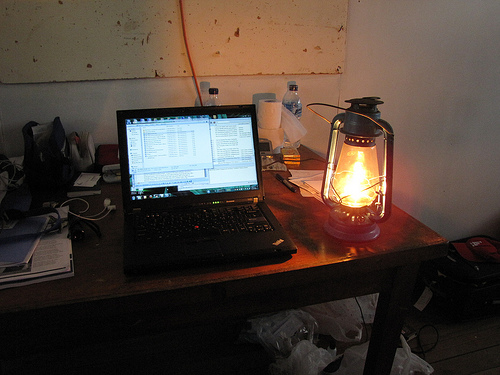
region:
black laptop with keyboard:
[108, 102, 305, 280]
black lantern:
[315, 77, 398, 272]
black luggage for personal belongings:
[445, 221, 495, 316]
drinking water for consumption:
[276, 67, 311, 169]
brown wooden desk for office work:
[1, 135, 457, 370]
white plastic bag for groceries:
[260, 315, 350, 370]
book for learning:
[0, 210, 80, 280]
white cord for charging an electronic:
[55, 185, 115, 235]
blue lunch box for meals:
[16, 115, 71, 215]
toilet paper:
[254, 92, 310, 173]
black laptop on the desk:
[116, 107, 297, 266]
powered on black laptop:
[118, 108, 296, 264]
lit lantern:
[318, 95, 398, 240]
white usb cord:
[73, 197, 122, 220]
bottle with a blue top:
[208, 84, 225, 104]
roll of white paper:
[258, 95, 290, 128]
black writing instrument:
[273, 167, 299, 195]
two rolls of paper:
[256, 95, 287, 139]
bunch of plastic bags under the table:
[245, 280, 367, 374]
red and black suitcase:
[447, 227, 496, 319]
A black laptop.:
[91, 100, 302, 287]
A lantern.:
[305, 90, 400, 255]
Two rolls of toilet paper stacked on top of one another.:
[250, 91, 285, 156]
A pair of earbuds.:
[55, 176, 115, 236]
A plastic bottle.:
[281, 80, 303, 125]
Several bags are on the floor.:
[245, 275, 461, 370]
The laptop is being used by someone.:
[100, 95, 290, 290]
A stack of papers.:
[0, 191, 80, 296]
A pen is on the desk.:
[265, 160, 310, 206]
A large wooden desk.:
[0, 102, 447, 337]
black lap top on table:
[75, 64, 320, 302]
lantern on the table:
[305, 88, 430, 262]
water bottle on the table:
[277, 72, 320, 155]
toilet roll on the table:
[243, 80, 312, 155]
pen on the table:
[265, 150, 303, 206]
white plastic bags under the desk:
[242, 289, 484, 374]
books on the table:
[0, 177, 89, 291]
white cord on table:
[44, 177, 155, 244]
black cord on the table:
[5, 178, 125, 269]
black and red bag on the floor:
[431, 227, 498, 309]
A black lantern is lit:
[301, 76, 442, 264]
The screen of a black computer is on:
[106, 97, 314, 294]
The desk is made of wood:
[21, 82, 423, 368]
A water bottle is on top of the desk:
[269, 70, 317, 162]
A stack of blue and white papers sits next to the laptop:
[10, 192, 97, 291]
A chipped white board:
[113, 7, 370, 87]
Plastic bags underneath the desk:
[227, 287, 442, 367]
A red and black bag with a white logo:
[418, 198, 493, 295]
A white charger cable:
[51, 177, 132, 238]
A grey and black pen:
[266, 162, 303, 194]